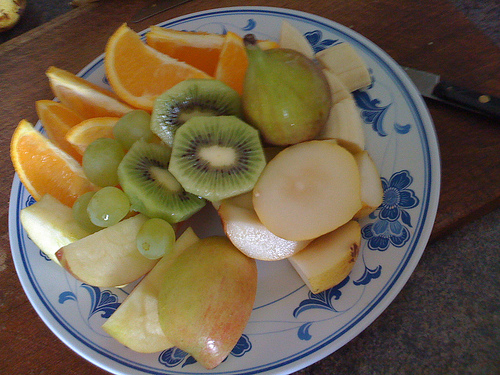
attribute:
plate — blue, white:
[358, 66, 439, 278]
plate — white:
[351, 260, 384, 285]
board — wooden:
[390, 13, 497, 139]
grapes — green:
[66, 105, 179, 262]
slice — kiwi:
[270, 154, 372, 245]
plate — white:
[16, 15, 454, 343]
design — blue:
[388, 70, 449, 182]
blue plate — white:
[386, 175, 433, 254]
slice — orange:
[209, 30, 253, 108]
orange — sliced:
[98, 20, 211, 100]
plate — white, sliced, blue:
[3, 3, 448, 373]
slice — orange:
[110, 37, 182, 87]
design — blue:
[392, 167, 409, 230]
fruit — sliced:
[18, 132, 96, 199]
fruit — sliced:
[102, 34, 227, 121]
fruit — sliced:
[60, 80, 303, 216]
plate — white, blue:
[181, 19, 493, 357]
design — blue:
[329, 129, 450, 297]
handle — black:
[430, 74, 484, 117]